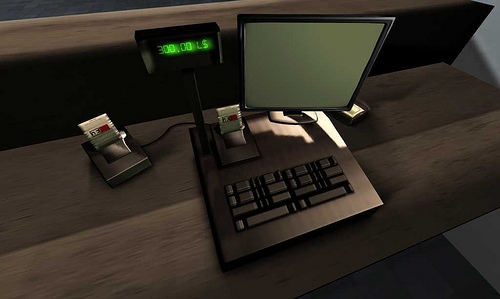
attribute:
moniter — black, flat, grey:
[234, 12, 392, 112]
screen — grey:
[242, 23, 349, 107]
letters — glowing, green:
[155, 37, 210, 60]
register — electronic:
[76, 14, 397, 273]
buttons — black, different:
[222, 155, 356, 234]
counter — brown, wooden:
[380, 60, 499, 229]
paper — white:
[78, 113, 122, 153]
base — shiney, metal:
[194, 112, 385, 272]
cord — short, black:
[137, 118, 190, 147]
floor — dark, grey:
[394, 253, 499, 295]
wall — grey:
[476, 26, 499, 83]